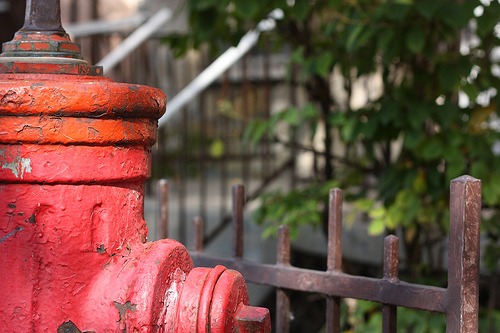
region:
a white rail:
[181, 53, 251, 106]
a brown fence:
[360, 247, 494, 318]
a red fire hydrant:
[10, 76, 146, 262]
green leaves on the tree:
[341, 105, 411, 147]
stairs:
[169, 156, 231, 211]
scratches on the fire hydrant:
[4, 148, 43, 183]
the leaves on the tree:
[351, 96, 426, 142]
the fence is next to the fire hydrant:
[286, 201, 492, 316]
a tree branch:
[311, 129, 357, 177]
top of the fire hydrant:
[15, 11, 82, 76]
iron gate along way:
[150, 158, 485, 321]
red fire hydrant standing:
[11, 5, 225, 332]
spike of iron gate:
[318, 182, 351, 266]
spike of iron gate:
[267, 231, 297, 269]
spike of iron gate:
[376, 230, 416, 275]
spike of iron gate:
[436, 158, 473, 329]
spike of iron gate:
[182, 216, 223, 247]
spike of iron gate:
[149, 179, 177, 231]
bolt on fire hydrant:
[236, 300, 276, 329]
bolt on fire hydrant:
[31, 0, 81, 42]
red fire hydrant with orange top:
[3, 0, 278, 330]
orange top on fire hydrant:
[0, 27, 168, 146]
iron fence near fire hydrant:
[234, 173, 494, 331]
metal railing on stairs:
[156, 5, 309, 250]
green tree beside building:
[163, 1, 499, 233]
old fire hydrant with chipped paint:
[4, 2, 266, 332]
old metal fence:
[273, 172, 483, 329]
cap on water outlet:
[171, 260, 274, 331]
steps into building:
[148, 162, 278, 253]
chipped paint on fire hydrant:
[106, 290, 146, 331]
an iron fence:
[183, 176, 492, 316]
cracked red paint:
[95, 260, 146, 324]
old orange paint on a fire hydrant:
[42, 89, 197, 151]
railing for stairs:
[120, 19, 294, 179]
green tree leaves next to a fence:
[261, 11, 439, 212]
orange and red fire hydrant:
[1, 37, 212, 331]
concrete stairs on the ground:
[149, 170, 294, 277]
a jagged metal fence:
[212, 150, 479, 331]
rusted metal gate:
[447, 185, 489, 331]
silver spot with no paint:
[8, 8, 100, 83]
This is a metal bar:
[440, 174, 496, 331]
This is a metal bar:
[375, 227, 410, 332]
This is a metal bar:
[322, 180, 346, 332]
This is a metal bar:
[267, 216, 305, 332]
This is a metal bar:
[226, 178, 258, 298]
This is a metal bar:
[188, 201, 214, 264]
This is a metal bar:
[153, 171, 175, 248]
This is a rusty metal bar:
[439, 168, 482, 331]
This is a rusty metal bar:
[370, 232, 415, 331]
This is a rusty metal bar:
[320, 180, 353, 332]